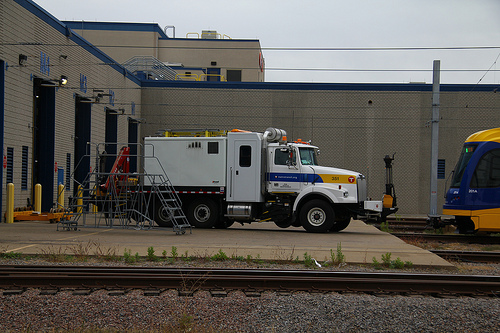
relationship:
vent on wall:
[22, 145, 29, 193] [1, 0, 144, 212]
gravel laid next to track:
[0, 289, 500, 333] [1, 263, 499, 302]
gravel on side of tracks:
[271, 289, 445, 316] [191, 249, 398, 296]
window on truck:
[275, 148, 296, 165] [137, 128, 389, 239]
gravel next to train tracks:
[0, 289, 500, 333] [0, 262, 500, 294]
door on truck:
[233, 140, 258, 202] [137, 128, 389, 239]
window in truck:
[273, 145, 296, 164] [137, 128, 389, 239]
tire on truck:
[298, 195, 335, 235] [137, 128, 389, 239]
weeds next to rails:
[12, 240, 418, 271] [0, 264, 500, 294]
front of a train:
[437, 124, 484, 241] [440, 127, 498, 237]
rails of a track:
[43, 259, 423, 296] [378, 175, 498, 266]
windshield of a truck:
[295, 144, 320, 166] [137, 128, 389, 239]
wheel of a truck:
[184, 195, 218, 227] [137, 128, 389, 239]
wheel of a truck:
[292, 197, 337, 233] [121, 133, 351, 248]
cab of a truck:
[263, 125, 366, 206] [142, 134, 382, 237]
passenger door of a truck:
[267, 144, 302, 188] [137, 128, 389, 239]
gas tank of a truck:
[224, 203, 254, 220] [137, 128, 389, 239]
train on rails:
[442, 126, 499, 243] [0, 264, 500, 294]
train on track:
[442, 126, 499, 243] [428, 247, 498, 263]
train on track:
[442, 126, 499, 243] [391, 232, 498, 244]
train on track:
[442, 126, 499, 243] [365, 219, 455, 233]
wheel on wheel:
[299, 199, 336, 233] [184, 198, 222, 230]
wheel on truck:
[299, 199, 336, 233] [87, 126, 399, 233]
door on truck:
[228, 138, 263, 205] [142, 134, 382, 237]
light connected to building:
[57, 75, 69, 96] [5, 1, 167, 235]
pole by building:
[4, 183, 22, 225] [9, 26, 85, 221]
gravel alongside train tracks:
[0, 289, 500, 333] [1, 264, 499, 298]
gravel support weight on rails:
[0, 289, 500, 333] [0, 264, 500, 294]